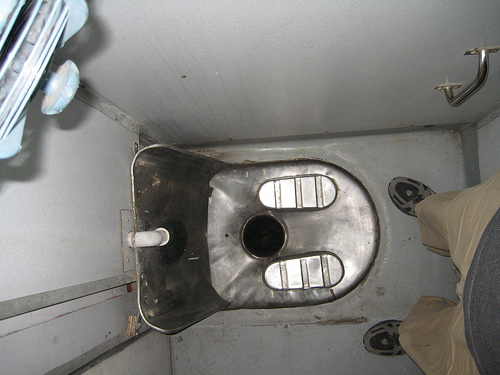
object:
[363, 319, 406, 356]
feet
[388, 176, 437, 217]
feet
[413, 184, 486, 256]
leg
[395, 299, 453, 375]
leg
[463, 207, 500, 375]
shirt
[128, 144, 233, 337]
lid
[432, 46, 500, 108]
handle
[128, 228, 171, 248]
pipe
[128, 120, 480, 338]
toilet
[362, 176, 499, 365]
man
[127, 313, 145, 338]
piece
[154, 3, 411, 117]
wall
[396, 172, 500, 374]
pants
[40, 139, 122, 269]
wall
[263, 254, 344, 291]
footprint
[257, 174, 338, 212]
footprint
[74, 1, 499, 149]
door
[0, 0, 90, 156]
thing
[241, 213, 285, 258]
hole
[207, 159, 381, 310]
seat